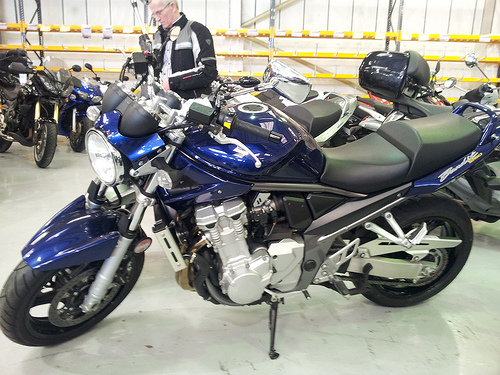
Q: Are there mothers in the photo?
A: No, there are no mothers.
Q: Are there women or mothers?
A: No, there are no mothers or women.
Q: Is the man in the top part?
A: Yes, the man is in the top of the image.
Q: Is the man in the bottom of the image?
A: No, the man is in the top of the image.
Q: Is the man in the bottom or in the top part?
A: The man is in the top of the image.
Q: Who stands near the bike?
A: The man stands near the bike.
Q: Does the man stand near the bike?
A: Yes, the man stands near the bike.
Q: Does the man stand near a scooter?
A: No, the man stands near the bike.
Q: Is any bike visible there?
A: Yes, there is a bike.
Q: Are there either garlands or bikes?
A: Yes, there is a bike.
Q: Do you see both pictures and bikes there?
A: No, there is a bike but no pictures.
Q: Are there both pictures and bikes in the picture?
A: No, there is a bike but no pictures.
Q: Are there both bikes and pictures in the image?
A: No, there is a bike but no pictures.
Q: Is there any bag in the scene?
A: No, there are no bags.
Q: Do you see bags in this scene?
A: No, there are no bags.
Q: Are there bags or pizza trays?
A: No, there are no bags or pizza trays.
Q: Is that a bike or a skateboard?
A: That is a bike.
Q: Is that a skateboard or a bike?
A: That is a bike.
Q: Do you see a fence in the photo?
A: No, there are no fences.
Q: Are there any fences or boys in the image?
A: No, there are no fences or boys.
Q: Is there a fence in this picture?
A: No, there are no fences.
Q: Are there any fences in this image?
A: No, there are no fences.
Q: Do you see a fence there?
A: No, there are no fences.